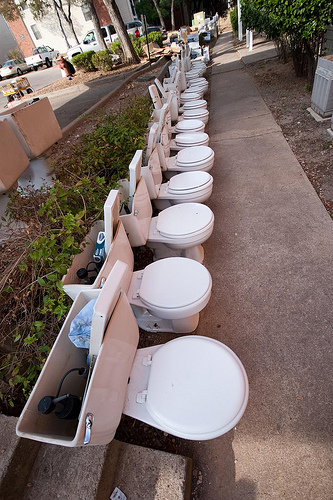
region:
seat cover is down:
[137, 348, 264, 450]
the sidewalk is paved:
[213, 110, 318, 381]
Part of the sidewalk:
[236, 155, 257, 210]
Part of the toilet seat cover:
[180, 380, 202, 402]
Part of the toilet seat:
[170, 312, 189, 316]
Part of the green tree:
[264, 11, 302, 22]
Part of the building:
[48, 35, 57, 43]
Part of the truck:
[33, 57, 42, 60]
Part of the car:
[7, 68, 11, 72]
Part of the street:
[36, 76, 49, 82]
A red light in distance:
[7, 65, 12, 70]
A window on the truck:
[82, 31, 96, 46]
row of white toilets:
[121, 75, 249, 440]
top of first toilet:
[149, 336, 241, 437]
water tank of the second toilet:
[62, 215, 135, 305]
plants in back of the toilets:
[0, 54, 172, 419]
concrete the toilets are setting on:
[93, 68, 328, 497]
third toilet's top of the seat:
[156, 203, 213, 234]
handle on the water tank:
[81, 413, 98, 444]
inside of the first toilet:
[23, 347, 95, 441]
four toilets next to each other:
[15, 148, 257, 449]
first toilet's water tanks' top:
[85, 258, 129, 357]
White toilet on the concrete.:
[16, 278, 252, 448]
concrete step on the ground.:
[0, 408, 196, 499]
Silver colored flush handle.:
[81, 414, 95, 450]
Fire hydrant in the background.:
[54, 51, 73, 79]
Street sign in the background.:
[136, 10, 155, 67]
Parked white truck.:
[22, 43, 54, 72]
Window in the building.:
[27, 22, 43, 42]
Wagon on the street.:
[2, 74, 32, 102]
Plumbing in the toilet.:
[35, 385, 84, 420]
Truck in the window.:
[82, 30, 97, 47]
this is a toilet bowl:
[131, 332, 257, 448]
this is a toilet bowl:
[132, 256, 218, 331]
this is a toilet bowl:
[156, 206, 224, 260]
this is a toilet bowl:
[151, 160, 220, 201]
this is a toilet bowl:
[169, 143, 216, 173]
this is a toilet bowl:
[173, 124, 214, 145]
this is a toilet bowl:
[169, 112, 206, 138]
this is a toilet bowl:
[178, 95, 208, 110]